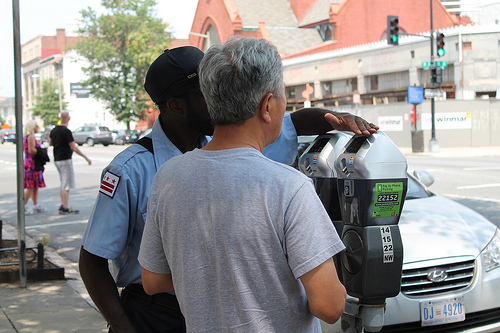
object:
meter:
[333, 130, 407, 332]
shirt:
[137, 146, 347, 331]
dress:
[22, 135, 47, 188]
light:
[391, 34, 397, 43]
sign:
[406, 85, 424, 153]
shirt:
[80, 112, 300, 296]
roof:
[224, 0, 331, 58]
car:
[291, 131, 499, 332]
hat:
[143, 46, 205, 103]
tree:
[63, 0, 175, 130]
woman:
[22, 121, 51, 216]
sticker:
[371, 181, 404, 216]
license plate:
[418, 293, 465, 327]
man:
[136, 33, 347, 332]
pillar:
[411, 129, 422, 153]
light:
[436, 48, 446, 57]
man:
[48, 110, 93, 214]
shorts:
[53, 158, 77, 190]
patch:
[98, 169, 122, 199]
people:
[78, 46, 380, 332]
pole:
[429, 1, 436, 138]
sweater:
[32, 146, 49, 173]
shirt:
[49, 124, 75, 161]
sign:
[467, 57, 500, 91]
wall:
[282, 26, 500, 146]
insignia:
[427, 267, 449, 283]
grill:
[400, 258, 477, 298]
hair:
[198, 32, 283, 126]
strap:
[136, 136, 155, 155]